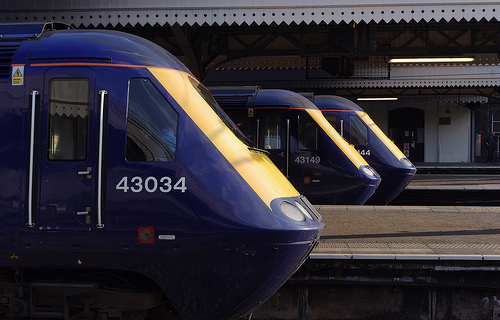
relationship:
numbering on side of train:
[116, 175, 187, 194] [4, 18, 326, 318]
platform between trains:
[325, 197, 497, 264] [0, 10, 417, 298]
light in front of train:
[279, 200, 315, 222] [0, 32, 355, 278]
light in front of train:
[277, 198, 306, 221] [0, 32, 355, 278]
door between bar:
[38, 68, 93, 229] [95, 90, 106, 229]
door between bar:
[38, 68, 93, 229] [27, 88, 39, 228]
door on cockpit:
[38, 68, 93, 229] [20, 36, 328, 319]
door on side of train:
[23, 54, 112, 247] [4, 18, 326, 318]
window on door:
[48, 77, 86, 161] [28, 67, 100, 232]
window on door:
[261, 110, 288, 152] [252, 113, 287, 172]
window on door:
[348, 113, 369, 150] [252, 113, 287, 172]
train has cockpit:
[4, 18, 326, 318] [37, 24, 272, 229]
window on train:
[126, 74, 193, 184] [4, 18, 326, 318]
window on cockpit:
[126, 74, 193, 184] [37, 24, 272, 229]